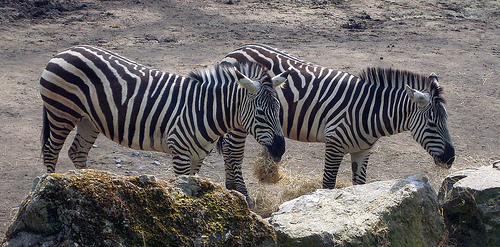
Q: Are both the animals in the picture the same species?
A: Yes, all the animals are zebras.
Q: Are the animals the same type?
A: Yes, all the animals are zebras.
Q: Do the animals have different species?
A: No, all the animals are zebras.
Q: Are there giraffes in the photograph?
A: No, there are no giraffes.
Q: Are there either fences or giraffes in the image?
A: No, there are no giraffes or fences.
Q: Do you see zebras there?
A: Yes, there is a zebra.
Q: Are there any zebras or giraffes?
A: Yes, there is a zebra.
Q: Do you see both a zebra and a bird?
A: No, there is a zebra but no birds.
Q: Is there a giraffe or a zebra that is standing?
A: Yes, the zebra is standing.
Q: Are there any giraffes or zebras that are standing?
A: Yes, the zebra is standing.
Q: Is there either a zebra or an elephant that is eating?
A: Yes, the zebra is eating.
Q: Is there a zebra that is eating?
A: Yes, there is a zebra that is eating.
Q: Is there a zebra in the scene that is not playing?
A: Yes, there is a zebra that is eating.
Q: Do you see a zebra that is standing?
A: Yes, there is a zebra that is standing.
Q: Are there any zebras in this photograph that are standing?
A: Yes, there is a zebra that is standing.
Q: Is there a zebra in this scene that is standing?
A: Yes, there is a zebra that is standing.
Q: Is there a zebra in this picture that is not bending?
A: Yes, there is a zebra that is standing.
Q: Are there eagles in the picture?
A: No, there are no eagles.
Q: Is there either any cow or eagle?
A: No, there are no eagles or cows.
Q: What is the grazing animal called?
A: The animal is a zebra.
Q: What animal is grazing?
A: The animal is a zebra.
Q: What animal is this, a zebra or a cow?
A: This is a zebra.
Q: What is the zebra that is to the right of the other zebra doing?
A: The zebra is eating.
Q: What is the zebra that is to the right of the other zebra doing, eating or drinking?
A: The zebra is eating.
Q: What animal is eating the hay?
A: The zebra is eating the hay.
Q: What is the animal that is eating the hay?
A: The animal is a zebra.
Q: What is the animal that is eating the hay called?
A: The animal is a zebra.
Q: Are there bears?
A: No, there are no bears.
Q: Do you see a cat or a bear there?
A: No, there are no bears or cats.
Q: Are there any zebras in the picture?
A: Yes, there is a zebra.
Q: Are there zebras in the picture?
A: Yes, there is a zebra.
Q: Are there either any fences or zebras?
A: Yes, there is a zebra.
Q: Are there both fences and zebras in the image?
A: No, there is a zebra but no fences.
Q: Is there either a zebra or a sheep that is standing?
A: Yes, the zebra is standing.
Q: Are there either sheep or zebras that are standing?
A: Yes, the zebra is standing.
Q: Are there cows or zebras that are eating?
A: Yes, the zebra is eating.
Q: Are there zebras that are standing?
A: Yes, there is a zebra that is standing.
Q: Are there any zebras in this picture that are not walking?
A: Yes, there is a zebra that is standing.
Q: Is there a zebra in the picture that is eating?
A: Yes, there is a zebra that is eating.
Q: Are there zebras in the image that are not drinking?
A: Yes, there is a zebra that is eating.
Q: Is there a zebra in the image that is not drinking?
A: Yes, there is a zebra that is eating.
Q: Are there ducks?
A: No, there are no ducks.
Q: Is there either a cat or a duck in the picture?
A: No, there are no ducks or cats.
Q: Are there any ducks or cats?
A: No, there are no ducks or cats.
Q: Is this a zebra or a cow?
A: This is a zebra.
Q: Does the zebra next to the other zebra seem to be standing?
A: Yes, the zebra is standing.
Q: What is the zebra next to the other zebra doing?
A: The zebra is standing.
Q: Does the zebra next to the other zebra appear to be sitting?
A: No, the zebra is standing.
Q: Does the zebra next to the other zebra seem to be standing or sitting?
A: The zebra is standing.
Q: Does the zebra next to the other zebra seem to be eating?
A: Yes, the zebra is eating.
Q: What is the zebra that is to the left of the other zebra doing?
A: The zebra is eating.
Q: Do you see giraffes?
A: No, there are no giraffes.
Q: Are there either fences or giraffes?
A: No, there are no giraffes or fences.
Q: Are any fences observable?
A: No, there are no fences.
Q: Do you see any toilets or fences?
A: No, there are no fences or toilets.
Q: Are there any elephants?
A: No, there are no elephants.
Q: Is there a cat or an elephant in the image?
A: No, there are no elephants or cats.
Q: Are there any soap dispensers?
A: No, there are no soap dispensers.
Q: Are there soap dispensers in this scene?
A: No, there are no soap dispensers.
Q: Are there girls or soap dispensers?
A: No, there are no soap dispensers or girls.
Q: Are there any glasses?
A: No, there are no glasses.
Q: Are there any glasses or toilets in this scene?
A: No, there are no glasses or toilets.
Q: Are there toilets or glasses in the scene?
A: No, there are no glasses or toilets.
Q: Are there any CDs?
A: No, there are no cds.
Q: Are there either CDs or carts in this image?
A: No, there are no CDs or carts.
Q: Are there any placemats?
A: No, there are no placemats.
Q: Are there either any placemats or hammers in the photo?
A: No, there are no placemats or hammers.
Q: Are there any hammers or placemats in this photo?
A: No, there are no placemats or hammers.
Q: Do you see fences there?
A: No, there are no fences.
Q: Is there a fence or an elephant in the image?
A: No, there are no fences or elephants.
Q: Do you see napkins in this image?
A: No, there are no napkins.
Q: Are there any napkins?
A: No, there are no napkins.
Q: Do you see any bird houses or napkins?
A: No, there are no napkins or bird houses.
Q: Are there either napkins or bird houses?
A: No, there are no napkins or bird houses.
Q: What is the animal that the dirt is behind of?
A: The animal is a zebra.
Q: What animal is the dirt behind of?
A: The dirt is behind the zebra.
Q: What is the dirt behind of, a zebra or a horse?
A: The dirt is behind a zebra.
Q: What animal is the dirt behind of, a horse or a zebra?
A: The dirt is behind a zebra.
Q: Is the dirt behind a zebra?
A: Yes, the dirt is behind a zebra.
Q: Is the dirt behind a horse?
A: No, the dirt is behind a zebra.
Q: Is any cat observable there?
A: No, there are no cats.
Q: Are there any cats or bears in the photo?
A: No, there are no cats or bears.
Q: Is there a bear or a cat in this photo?
A: No, there are no cats or bears.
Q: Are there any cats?
A: No, there are no cats.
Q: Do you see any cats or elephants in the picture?
A: No, there are no cats or elephants.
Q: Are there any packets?
A: No, there are no packets.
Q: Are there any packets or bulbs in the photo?
A: No, there are no packets or bulbs.